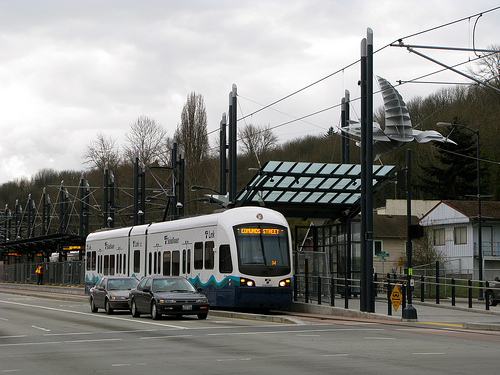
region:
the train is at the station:
[82, 207, 294, 296]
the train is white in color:
[86, 206, 293, 299]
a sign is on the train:
[238, 224, 287, 237]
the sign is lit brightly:
[240, 225, 283, 234]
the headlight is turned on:
[243, 280, 255, 287]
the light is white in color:
[248, 280, 253, 288]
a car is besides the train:
[126, 278, 203, 318]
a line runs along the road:
[4, 294, 191, 340]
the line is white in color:
[3, 297, 191, 335]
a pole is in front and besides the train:
[352, 38, 386, 320]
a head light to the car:
[149, 292, 197, 319]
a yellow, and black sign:
[385, 287, 412, 312]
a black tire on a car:
[141, 299, 171, 325]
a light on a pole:
[180, 175, 219, 201]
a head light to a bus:
[233, 266, 284, 309]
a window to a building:
[447, 225, 469, 247]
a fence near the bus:
[304, 244, 341, 277]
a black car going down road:
[144, 285, 180, 312]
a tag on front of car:
[178, 303, 204, 314]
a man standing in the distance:
[30, 265, 57, 280]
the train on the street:
[73, 199, 332, 299]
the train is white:
[76, 222, 285, 298]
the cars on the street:
[61, 270, 211, 338]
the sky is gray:
[11, 14, 70, 59]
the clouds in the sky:
[21, 8, 230, 91]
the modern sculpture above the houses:
[372, 78, 448, 160]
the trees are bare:
[173, 96, 225, 192]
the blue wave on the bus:
[195, 269, 238, 288]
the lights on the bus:
[233, 273, 299, 293]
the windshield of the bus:
[234, 240, 287, 269]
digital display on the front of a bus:
[233, 228, 285, 238]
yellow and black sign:
[382, 276, 408, 314]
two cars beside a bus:
[89, 265, 209, 325]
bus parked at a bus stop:
[72, 196, 299, 308]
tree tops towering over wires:
[61, 78, 261, 180]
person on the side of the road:
[32, 261, 53, 287]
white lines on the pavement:
[54, 302, 128, 373]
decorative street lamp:
[362, 71, 447, 350]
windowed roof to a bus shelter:
[264, 156, 379, 218]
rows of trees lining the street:
[18, 61, 338, 216]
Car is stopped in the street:
[125, 272, 212, 320]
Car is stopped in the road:
[125, 272, 212, 321]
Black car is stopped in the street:
[127, 273, 209, 322]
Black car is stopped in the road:
[128, 273, 213, 321]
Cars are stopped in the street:
[86, 272, 210, 322]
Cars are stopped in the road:
[87, 275, 212, 322]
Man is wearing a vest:
[32, 261, 47, 276]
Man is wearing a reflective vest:
[35, 263, 44, 275]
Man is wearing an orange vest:
[32, 262, 44, 274]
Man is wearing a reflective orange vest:
[32, 261, 45, 273]